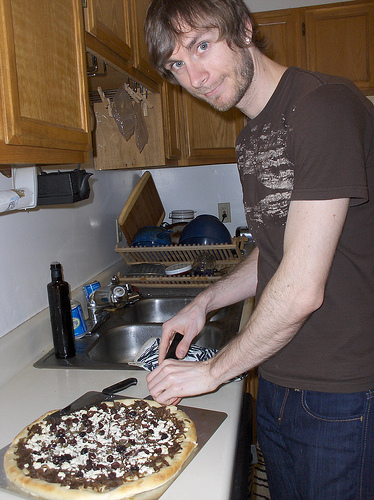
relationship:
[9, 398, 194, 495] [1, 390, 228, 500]
pizza on tray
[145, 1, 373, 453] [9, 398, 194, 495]
man cutting pizza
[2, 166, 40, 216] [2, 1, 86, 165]
dispenser on cabinet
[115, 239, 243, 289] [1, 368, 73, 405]
strainer on counter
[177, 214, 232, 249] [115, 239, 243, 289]
bowl in strainer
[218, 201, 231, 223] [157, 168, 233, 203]
outlet on wall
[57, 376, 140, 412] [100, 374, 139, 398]
knife with handle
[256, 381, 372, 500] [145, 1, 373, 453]
jeans on man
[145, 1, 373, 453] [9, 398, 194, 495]
man slicing pizza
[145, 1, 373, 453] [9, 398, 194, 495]
man touching pizza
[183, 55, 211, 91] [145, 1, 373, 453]
nose on man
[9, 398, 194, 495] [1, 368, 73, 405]
pizza on counter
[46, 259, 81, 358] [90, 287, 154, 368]
bottle on sink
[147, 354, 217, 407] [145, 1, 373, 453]
hand of man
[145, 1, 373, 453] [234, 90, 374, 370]
man in shirt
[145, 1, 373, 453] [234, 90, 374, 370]
man wearing shirt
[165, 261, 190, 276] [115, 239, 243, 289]
lid in strainer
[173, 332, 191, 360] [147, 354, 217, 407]
thumb on hand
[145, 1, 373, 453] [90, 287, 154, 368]
man near sink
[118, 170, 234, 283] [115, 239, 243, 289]
dishes in strainer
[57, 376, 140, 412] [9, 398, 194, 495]
knife by pizza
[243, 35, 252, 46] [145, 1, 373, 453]
earing on man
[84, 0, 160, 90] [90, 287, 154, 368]
cabinet above sink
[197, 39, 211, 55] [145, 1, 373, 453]
eyes on man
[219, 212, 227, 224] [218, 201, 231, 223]
plug in outlet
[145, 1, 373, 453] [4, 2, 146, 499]
man in kitchen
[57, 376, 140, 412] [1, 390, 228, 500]
knife on tray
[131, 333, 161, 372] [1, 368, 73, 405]
towel on counter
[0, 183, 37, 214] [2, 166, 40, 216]
towel on dispenser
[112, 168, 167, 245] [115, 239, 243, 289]
cutting-board in strainer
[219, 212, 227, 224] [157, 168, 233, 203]
plug in wall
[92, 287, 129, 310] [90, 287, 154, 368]
faucet over sink